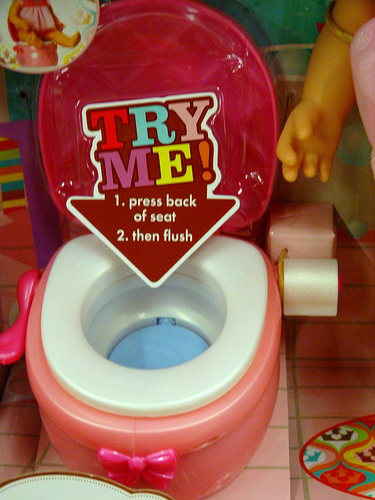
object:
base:
[38, 348, 279, 500]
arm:
[277, 0, 374, 183]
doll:
[275, 0, 374, 184]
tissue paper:
[282, 257, 339, 318]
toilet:
[7, 12, 64, 67]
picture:
[0, 0, 100, 75]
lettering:
[114, 193, 197, 242]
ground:
[317, 83, 340, 109]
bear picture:
[8, 0, 82, 50]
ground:
[301, 110, 340, 145]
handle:
[0, 268, 44, 366]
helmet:
[36, 3, 279, 237]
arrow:
[66, 88, 238, 288]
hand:
[276, 100, 337, 182]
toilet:
[22, 233, 283, 499]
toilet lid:
[36, 0, 279, 238]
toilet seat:
[39, 232, 269, 417]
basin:
[24, 0, 282, 500]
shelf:
[11, 336, 314, 495]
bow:
[97, 447, 177, 491]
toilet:
[0, 0, 297, 488]